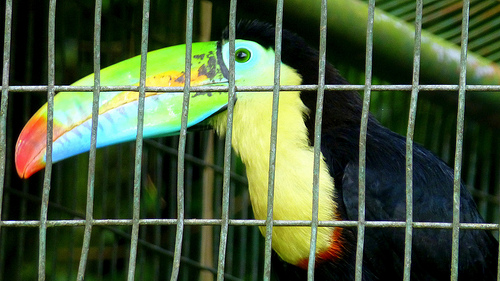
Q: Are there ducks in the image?
A: No, there are no ducks.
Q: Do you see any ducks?
A: No, there are no ducks.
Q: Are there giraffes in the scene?
A: No, there are no giraffes.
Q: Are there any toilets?
A: No, there are no toilets.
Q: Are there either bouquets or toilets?
A: No, there are no toilets or bouquets.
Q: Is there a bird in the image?
A: Yes, there is a bird.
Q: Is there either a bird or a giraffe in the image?
A: Yes, there is a bird.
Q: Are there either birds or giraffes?
A: Yes, there is a bird.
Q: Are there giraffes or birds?
A: Yes, there is a bird.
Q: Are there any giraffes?
A: No, there are no giraffes.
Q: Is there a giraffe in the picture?
A: No, there are no giraffes.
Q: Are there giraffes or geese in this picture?
A: No, there are no giraffes or geese.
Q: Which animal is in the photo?
A: The animal is a bird.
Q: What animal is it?
A: The animal is a bird.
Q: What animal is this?
A: This is a bird.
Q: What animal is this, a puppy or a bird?
A: This is a bird.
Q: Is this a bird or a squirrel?
A: This is a bird.